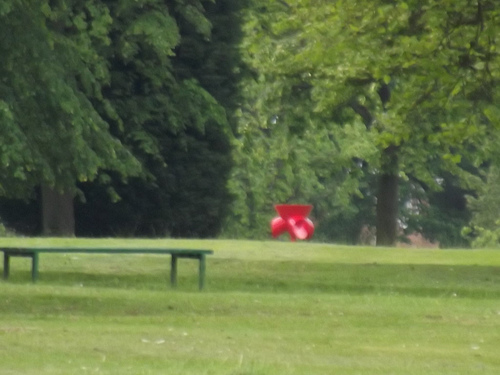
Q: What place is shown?
A: It is a field.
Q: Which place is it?
A: It is a field.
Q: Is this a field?
A: Yes, it is a field.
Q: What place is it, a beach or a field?
A: It is a field.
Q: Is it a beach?
A: No, it is a field.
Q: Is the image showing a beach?
A: No, the picture is showing a field.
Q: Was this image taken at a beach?
A: No, the picture was taken in a field.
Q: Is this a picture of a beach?
A: No, the picture is showing a field.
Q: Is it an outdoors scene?
A: Yes, it is outdoors.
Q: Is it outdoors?
A: Yes, it is outdoors.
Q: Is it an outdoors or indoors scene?
A: It is outdoors.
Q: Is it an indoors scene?
A: No, it is outdoors.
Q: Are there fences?
A: No, there are no fences.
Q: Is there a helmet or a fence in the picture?
A: No, there are no fences or helmets.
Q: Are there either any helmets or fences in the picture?
A: No, there are no fences or helmets.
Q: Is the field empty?
A: Yes, the field is empty.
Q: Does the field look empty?
A: Yes, the field is empty.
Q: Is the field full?
A: No, the field is empty.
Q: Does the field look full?
A: No, the field is empty.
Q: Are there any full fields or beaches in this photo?
A: No, there is a field but it is empty.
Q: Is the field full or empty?
A: The field is empty.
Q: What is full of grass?
A: The field is full of grass.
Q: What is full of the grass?
A: The field is full of grass.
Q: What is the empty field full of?
A: The field is full of grass.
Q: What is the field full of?
A: The field is full of grass.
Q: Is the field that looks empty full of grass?
A: Yes, the field is full of grass.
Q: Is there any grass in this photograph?
A: Yes, there is grass.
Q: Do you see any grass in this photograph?
A: Yes, there is grass.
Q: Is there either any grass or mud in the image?
A: Yes, there is grass.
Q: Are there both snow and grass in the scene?
A: No, there is grass but no snow.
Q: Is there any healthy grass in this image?
A: Yes, there is healthy grass.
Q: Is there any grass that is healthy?
A: Yes, there is grass that is healthy.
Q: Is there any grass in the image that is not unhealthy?
A: Yes, there is healthy grass.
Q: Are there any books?
A: No, there are no books.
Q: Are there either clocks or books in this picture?
A: No, there are no books or clocks.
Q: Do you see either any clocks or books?
A: No, there are no books or clocks.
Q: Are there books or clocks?
A: No, there are no books or clocks.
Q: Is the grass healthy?
A: Yes, the grass is healthy.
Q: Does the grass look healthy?
A: Yes, the grass is healthy.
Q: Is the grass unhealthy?
A: No, the grass is healthy.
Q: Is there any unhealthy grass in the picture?
A: No, there is grass but it is healthy.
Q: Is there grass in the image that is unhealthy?
A: No, there is grass but it is healthy.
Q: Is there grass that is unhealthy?
A: No, there is grass but it is healthy.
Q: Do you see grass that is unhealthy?
A: No, there is grass but it is healthy.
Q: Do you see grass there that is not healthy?
A: No, there is grass but it is healthy.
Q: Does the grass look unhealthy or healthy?
A: The grass is healthy.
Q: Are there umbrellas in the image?
A: No, there are no umbrellas.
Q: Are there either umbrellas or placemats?
A: No, there are no umbrellas or placemats.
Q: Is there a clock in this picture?
A: No, there are no clocks.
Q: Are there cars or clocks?
A: No, there are no clocks or cars.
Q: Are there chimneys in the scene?
A: No, there are no chimneys.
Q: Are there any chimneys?
A: No, there are no chimneys.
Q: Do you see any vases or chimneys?
A: No, there are no chimneys or vases.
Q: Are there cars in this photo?
A: No, there are no cars.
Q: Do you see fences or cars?
A: No, there are no cars or fences.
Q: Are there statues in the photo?
A: No, there are no statues.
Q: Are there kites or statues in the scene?
A: No, there are no statues or kites.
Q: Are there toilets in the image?
A: No, there are no toilets.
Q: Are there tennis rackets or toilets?
A: No, there are no toilets or tennis rackets.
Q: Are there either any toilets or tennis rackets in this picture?
A: No, there are no toilets or tennis rackets.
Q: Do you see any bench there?
A: Yes, there is a bench.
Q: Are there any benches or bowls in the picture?
A: Yes, there is a bench.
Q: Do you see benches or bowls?
A: Yes, there is a bench.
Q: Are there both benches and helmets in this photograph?
A: No, there is a bench but no helmets.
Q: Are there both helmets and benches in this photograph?
A: No, there is a bench but no helmets.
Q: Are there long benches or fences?
A: Yes, there is a long bench.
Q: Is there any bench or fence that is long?
A: Yes, the bench is long.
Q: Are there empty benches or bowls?
A: Yes, there is an empty bench.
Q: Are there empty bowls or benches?
A: Yes, there is an empty bench.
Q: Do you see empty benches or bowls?
A: Yes, there is an empty bench.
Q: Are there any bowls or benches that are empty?
A: Yes, the bench is empty.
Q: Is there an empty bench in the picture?
A: Yes, there is an empty bench.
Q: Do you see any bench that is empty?
A: Yes, there is a bench that is empty.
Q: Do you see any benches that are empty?
A: Yes, there is a bench that is empty.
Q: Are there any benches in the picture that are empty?
A: Yes, there is a bench that is empty.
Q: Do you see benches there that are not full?
A: Yes, there is a empty bench.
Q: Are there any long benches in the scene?
A: Yes, there is a long bench.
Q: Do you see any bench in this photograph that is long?
A: Yes, there is a bench that is long.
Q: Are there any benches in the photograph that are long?
A: Yes, there is a bench that is long.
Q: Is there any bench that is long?
A: Yes, there is a bench that is long.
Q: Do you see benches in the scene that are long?
A: Yes, there is a bench that is long.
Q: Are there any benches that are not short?
A: Yes, there is a long bench.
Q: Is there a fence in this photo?
A: No, there are no fences.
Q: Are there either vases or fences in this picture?
A: No, there are no fences or vases.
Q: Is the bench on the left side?
A: Yes, the bench is on the left of the image.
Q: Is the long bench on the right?
A: No, the bench is on the left of the image.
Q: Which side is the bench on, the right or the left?
A: The bench is on the left of the image.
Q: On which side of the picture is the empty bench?
A: The bench is on the left of the image.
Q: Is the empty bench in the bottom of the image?
A: Yes, the bench is in the bottom of the image.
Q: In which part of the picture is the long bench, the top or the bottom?
A: The bench is in the bottom of the image.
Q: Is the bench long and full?
A: No, the bench is long but empty.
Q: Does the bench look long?
A: Yes, the bench is long.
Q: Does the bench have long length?
A: Yes, the bench is long.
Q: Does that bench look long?
A: Yes, the bench is long.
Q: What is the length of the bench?
A: The bench is long.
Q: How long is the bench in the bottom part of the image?
A: The bench is long.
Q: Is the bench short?
A: No, the bench is long.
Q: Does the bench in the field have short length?
A: No, the bench is long.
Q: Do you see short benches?
A: No, there is a bench but it is long.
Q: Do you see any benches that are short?
A: No, there is a bench but it is long.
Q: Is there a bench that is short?
A: No, there is a bench but it is long.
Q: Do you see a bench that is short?
A: No, there is a bench but it is long.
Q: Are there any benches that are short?
A: No, there is a bench but it is long.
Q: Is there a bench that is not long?
A: No, there is a bench but it is long.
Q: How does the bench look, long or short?
A: The bench is long.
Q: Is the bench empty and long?
A: Yes, the bench is empty and long.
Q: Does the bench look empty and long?
A: Yes, the bench is empty and long.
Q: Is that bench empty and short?
A: No, the bench is empty but long.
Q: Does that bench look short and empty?
A: No, the bench is empty but long.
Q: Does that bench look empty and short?
A: No, the bench is empty but long.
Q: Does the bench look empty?
A: Yes, the bench is empty.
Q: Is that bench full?
A: No, the bench is empty.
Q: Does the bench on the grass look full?
A: No, the bench is empty.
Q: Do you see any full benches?
A: No, there is a bench but it is empty.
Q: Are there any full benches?
A: No, there is a bench but it is empty.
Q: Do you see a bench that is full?
A: No, there is a bench but it is empty.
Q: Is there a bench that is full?
A: No, there is a bench but it is empty.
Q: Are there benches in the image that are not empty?
A: No, there is a bench but it is empty.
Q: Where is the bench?
A: The bench is on the grass.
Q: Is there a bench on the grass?
A: Yes, there is a bench on the grass.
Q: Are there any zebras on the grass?
A: No, there is a bench on the grass.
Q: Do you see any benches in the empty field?
A: Yes, there is a bench in the field.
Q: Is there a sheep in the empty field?
A: No, there is a bench in the field.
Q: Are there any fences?
A: No, there are no fences.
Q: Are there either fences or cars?
A: No, there are no fences or cars.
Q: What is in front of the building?
A: The tree is in front of the building.